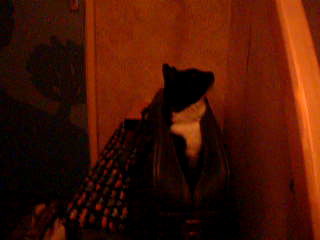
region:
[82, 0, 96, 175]
a white door frame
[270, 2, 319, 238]
a stair rail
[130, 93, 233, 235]
a black leather bag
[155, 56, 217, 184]
a black and white cat in a bag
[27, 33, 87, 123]
a tree painted on a wall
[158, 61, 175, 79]
the ear of a cat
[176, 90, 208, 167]
the white neck and chest of a cat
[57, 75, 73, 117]
the trunk of a tree painted on a wall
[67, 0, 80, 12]
a thermostat on a wall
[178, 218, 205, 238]
the strap attachment on a black bag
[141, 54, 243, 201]
black and white cat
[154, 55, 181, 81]
black ears on cat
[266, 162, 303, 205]
black spot on wall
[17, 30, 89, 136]
design on wall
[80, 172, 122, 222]
pattern on piece of clothing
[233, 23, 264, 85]
large black scratch on wall paint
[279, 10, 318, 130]
white wooden guard rail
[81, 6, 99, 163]
beige wooden door framing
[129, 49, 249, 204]
black and white cat staring at wall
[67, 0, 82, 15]
light switch fixture on wall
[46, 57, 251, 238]
items sitting on a table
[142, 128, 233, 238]
a red bag on the table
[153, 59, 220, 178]
a cat in the bag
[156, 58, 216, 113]
the cat's head is black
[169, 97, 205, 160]
the cat's body is white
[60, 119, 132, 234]
the bag is patterned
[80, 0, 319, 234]
the wall section seems white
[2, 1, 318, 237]
the corner is dark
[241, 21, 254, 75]
a spot on the wall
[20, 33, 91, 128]
a tree shape on the wall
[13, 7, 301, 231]
dark, shadowy photo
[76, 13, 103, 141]
a wooden door frame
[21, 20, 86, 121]
design drawn in the other room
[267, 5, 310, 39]
rail of a bannister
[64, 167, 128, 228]
ornate lamp shade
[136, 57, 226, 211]
black and white cat inside a bag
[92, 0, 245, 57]
wall behind the cat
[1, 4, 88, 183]
dark room next door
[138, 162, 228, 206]
bottom half of a leather bag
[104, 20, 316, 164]
cat looks up toward the stairway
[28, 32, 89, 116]
There is shadow in the background.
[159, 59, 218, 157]
This is a cat.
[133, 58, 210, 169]
The cat is black and white.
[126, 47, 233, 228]
The cat is in a bag.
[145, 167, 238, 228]
This is a bag.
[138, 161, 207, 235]
The bag is brown.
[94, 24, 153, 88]
The wall is orange.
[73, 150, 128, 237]
This bag is patterned.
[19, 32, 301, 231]
This photo is dark.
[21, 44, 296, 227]
This photo is blurry.